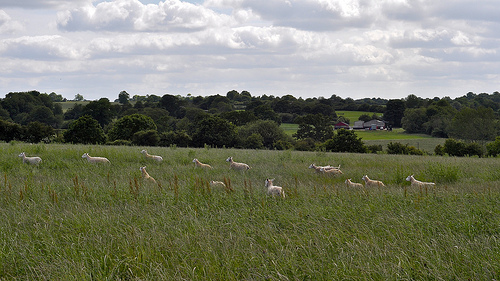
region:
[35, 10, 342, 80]
Clouds are in the sky.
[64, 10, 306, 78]
The clouds are gray and white.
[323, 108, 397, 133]
Buildings are in the background.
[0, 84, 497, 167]
Trees are in the background.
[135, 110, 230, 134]
The trees are green.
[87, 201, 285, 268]
The grass is green.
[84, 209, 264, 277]
The grass is tall.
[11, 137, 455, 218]
Sheep are in the grass.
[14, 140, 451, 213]
The sheep are white.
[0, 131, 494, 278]
The sheep are in a field.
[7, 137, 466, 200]
sheep in a field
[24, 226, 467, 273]
green grass of a field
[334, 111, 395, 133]
barn in the background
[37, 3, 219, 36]
white clouds in the sky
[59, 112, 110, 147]
green tree beyond the grasses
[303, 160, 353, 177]
two white sheep in grass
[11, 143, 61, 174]
a sheep walking towards the left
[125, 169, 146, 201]
brown weeds in the grass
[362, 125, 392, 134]
cars parked near a barn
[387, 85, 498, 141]
cluster of trees with green leaves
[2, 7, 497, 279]
a scene outside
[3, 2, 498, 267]
a scene during the day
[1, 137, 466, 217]
a row of animals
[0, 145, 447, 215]
a flock of white sheep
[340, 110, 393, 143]
a house in the background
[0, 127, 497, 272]
a green pasture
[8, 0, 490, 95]
some clouds in the sky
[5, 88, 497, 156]
a row of trees in the distance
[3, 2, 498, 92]
a sky with an overcast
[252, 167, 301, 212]
a lone sheep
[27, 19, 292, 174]
the sky is clear and visible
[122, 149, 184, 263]
the grass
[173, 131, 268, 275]
the grass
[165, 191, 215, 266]
the grass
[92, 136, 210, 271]
the grass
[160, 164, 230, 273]
the grass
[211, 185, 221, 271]
the grass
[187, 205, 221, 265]
the grass